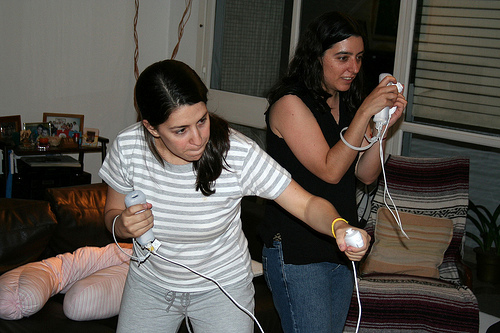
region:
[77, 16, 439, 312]
women holding remote controls for electronic game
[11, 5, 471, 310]
room with a table, chair and sofa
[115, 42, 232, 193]
woman playing with lips tightly together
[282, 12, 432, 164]
woman smiling with lips apart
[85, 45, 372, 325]
woman leaning forward with hands apart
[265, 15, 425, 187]
woman standing straight with hands together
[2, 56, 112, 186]
table filled with pictures in frames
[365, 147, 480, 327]
pillow with tan stripes on brown and tan blanket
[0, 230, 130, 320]
pink and white striped pillows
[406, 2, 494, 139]
blinds covering a window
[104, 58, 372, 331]
A girl in a striped shirt with dark brown hair.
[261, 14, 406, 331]
A girl in a black shirt and denim blue jeans.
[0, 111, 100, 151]
Family photos on a shelf.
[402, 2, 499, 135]
Blinds on a window beside the girl in black.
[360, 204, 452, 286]
A tan and white pillow on a chair.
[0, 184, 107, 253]
Dark colored leather pillows of a couch.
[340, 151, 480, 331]
A striped blanket laying over a chair.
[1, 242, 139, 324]
A body pillow lying on a couch.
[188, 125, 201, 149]
The nose of a woman in a striped shirt.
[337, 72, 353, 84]
Smiling mouth of a girl in a black shirt.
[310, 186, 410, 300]
The girl has a Wii remote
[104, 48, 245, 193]
The girl has black hair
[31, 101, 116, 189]
There is a photo in the back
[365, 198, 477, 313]
The pillow is light colored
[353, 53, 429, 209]
The woman has her hands together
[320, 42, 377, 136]
The woman is smiling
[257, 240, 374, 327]
The woman has on jeans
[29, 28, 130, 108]
The wall is white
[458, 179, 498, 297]
The plant is in the back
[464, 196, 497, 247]
The plant is green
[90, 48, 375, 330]
young girl on left with gaming controls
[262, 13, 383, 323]
young woman on right with gaming controls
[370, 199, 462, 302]
shirt with pillow on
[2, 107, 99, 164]
photographs on the table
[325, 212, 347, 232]
yellow bangle on girls left hand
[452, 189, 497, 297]
pot plant on floor on the ride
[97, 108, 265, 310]
striped shirt worn by young woman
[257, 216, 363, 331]
jeans worn by young woman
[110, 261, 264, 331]
sweatpants worn by girl on left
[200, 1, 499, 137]
windows on the right of the room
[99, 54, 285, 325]
Woman in gray and white stripe shirt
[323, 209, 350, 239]
Yellow band on woman's arm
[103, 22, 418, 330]
Two women playing video game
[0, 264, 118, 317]
Pink and white pillow on couch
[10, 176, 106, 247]
Brown leather sofa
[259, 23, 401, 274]
Woman wearing black top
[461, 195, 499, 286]
Plant on floor in background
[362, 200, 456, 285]
Striped pillow on chair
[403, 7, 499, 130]
Cream blinds on window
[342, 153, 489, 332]
Striped blanket on chair